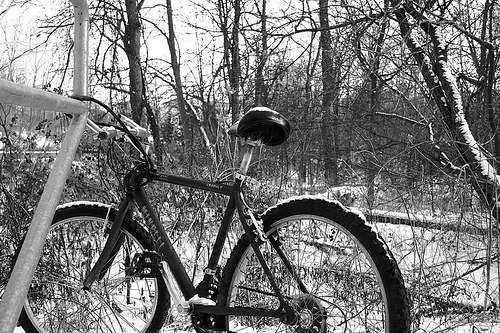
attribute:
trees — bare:
[125, 2, 489, 192]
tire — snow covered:
[210, 177, 417, 331]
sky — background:
[2, 0, 497, 120]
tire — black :
[259, 187, 396, 262]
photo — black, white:
[8, 33, 495, 331]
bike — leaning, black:
[9, 90, 416, 330]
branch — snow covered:
[389, 24, 499, 189]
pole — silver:
[0, 1, 94, 331]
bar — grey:
[15, 10, 100, 232]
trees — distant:
[2, 1, 499, 208]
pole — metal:
[0, 77, 87, 114]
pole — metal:
[69, 0, 91, 99]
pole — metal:
[0, 114, 87, 331]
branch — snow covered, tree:
[390, 3, 499, 218]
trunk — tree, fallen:
[188, 139, 453, 267]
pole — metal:
[0, 74, 85, 314]